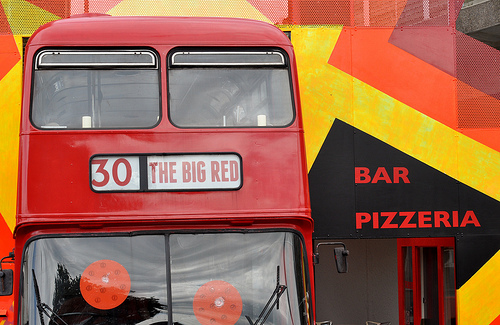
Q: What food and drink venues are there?
A: Bar and pizzeria.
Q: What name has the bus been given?
A: The big red.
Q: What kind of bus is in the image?
A: A double decker.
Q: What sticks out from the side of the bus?
A: Mirror.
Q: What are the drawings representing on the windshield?
A: Pizzas.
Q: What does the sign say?
A: Bar pizzeria.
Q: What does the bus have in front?
A: 4 windows.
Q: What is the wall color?
A: Orange and red.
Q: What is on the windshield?
A: Circles.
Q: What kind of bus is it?
A: Double decker.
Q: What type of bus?
A: Double decker.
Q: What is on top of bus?
A: Window.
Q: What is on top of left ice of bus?
A: Window.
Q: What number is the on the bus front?
A: 30.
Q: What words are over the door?
A: BAR PIZZERIA.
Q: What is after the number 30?
A: THE BIG RED.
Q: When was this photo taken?
A: During the day.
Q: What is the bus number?
A: 30.